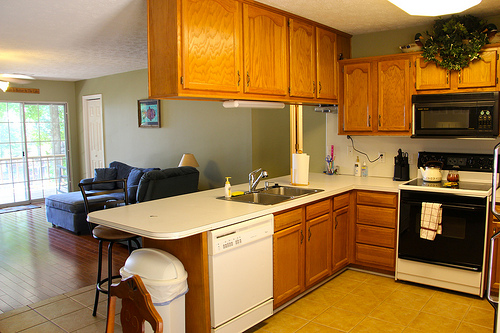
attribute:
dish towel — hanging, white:
[418, 197, 444, 242]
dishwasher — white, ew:
[207, 213, 275, 332]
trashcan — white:
[118, 247, 190, 332]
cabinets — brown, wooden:
[146, 1, 499, 138]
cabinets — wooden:
[273, 191, 351, 313]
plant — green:
[417, 13, 490, 71]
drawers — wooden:
[354, 191, 396, 271]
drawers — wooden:
[272, 193, 350, 228]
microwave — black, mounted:
[410, 91, 498, 139]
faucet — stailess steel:
[248, 163, 268, 192]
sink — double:
[217, 182, 323, 205]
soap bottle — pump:
[221, 174, 232, 198]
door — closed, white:
[83, 97, 105, 179]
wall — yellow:
[250, 103, 325, 181]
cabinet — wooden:
[180, 0, 289, 101]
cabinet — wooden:
[289, 14, 339, 102]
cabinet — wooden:
[336, 57, 411, 136]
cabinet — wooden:
[273, 214, 332, 304]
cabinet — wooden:
[411, 47, 498, 92]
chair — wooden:
[101, 274, 165, 332]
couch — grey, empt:
[44, 160, 199, 250]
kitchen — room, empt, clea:
[88, 1, 499, 333]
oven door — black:
[397, 186, 487, 273]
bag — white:
[119, 265, 188, 309]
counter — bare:
[86, 170, 410, 240]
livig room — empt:
[0, 1, 252, 315]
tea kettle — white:
[419, 157, 442, 183]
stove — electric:
[401, 176, 491, 193]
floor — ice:
[240, 269, 494, 331]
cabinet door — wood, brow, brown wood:
[180, 1, 240, 93]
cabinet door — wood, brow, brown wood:
[242, 2, 288, 96]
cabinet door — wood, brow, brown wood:
[288, 16, 315, 100]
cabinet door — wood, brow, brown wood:
[373, 55, 411, 133]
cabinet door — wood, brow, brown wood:
[316, 27, 339, 103]